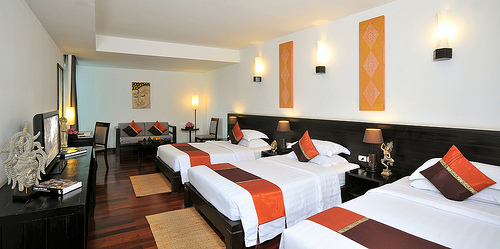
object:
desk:
[69, 131, 95, 146]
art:
[3, 130, 51, 192]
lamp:
[191, 93, 203, 137]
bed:
[178, 136, 366, 249]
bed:
[281, 153, 500, 249]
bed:
[152, 126, 277, 194]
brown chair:
[89, 120, 110, 161]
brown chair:
[194, 117, 219, 143]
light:
[312, 40, 335, 74]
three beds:
[157, 120, 500, 248]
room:
[0, 1, 499, 249]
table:
[343, 167, 396, 199]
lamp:
[361, 127, 386, 173]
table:
[258, 148, 293, 158]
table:
[180, 127, 198, 142]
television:
[31, 109, 69, 174]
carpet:
[143, 206, 225, 248]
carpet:
[128, 172, 173, 199]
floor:
[90, 149, 280, 245]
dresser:
[0, 145, 100, 239]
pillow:
[122, 118, 143, 137]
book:
[22, 153, 120, 236]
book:
[35, 177, 81, 196]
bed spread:
[192, 156, 346, 248]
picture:
[131, 80, 152, 110]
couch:
[115, 121, 176, 150]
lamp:
[226, 115, 239, 136]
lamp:
[276, 120, 290, 153]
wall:
[76, 61, 199, 125]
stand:
[60, 155, 90, 185]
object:
[8, 121, 47, 208]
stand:
[46, 155, 66, 175]